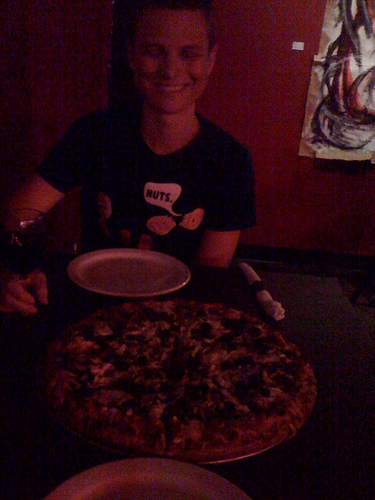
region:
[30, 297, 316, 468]
the pizza sitting on the table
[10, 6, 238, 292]
the guy sitting next to the table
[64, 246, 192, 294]
the plate sitting on the table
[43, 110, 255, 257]
the silly tshirt the man has on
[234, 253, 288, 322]
a rolled up napkin with a ring around it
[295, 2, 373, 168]
the piece of paper on the wall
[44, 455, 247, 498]
another white plate on the table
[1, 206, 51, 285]
the wine glass the man is holding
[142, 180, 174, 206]
the writing on the shirt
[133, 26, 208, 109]
the man's happy face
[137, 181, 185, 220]
speech bubble on a shirt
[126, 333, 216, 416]
cheese on a pizza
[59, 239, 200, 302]
circular white plate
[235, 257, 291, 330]
silverware in a napkin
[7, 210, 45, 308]
wine glass filled with red wine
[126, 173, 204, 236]
design on a t shirt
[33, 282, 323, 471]
pizza on a table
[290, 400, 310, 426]
crust on a pizza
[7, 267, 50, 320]
hand holding a wine stem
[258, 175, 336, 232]
wooden wall in a restaurant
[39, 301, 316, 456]
A pizza on the table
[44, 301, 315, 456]
The pizza is cooked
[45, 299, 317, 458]
The pizza is circular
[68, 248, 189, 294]
A plate on the table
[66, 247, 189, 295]
The plate is empty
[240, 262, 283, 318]
A napkin near the pizza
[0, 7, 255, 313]
A man at the table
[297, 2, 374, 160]
A painting on the wall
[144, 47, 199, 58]
The eyes of the man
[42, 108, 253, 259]
The man is wearing a black shirt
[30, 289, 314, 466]
Pizza with lots of olives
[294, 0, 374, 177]
abstract painting in background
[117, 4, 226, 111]
smiling person with eyes closed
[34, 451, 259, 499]
part of a plate can be seen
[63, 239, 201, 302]
empty plate in front of person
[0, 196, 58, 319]
the person's hand holds a glass of wine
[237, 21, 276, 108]
the walls appear red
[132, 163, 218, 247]
the word nuts on persons shirt with cartoon of nuts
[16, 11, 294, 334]
most of the image is red and very noisy/grainy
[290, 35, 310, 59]
small white square attached to wall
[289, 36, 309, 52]
a white sticker on the wall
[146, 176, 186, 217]
a conversation bubble on a t-shirt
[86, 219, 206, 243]
a peanut logo on shirt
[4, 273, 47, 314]
a hand holding a glass of wine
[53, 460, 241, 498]
an empty white plate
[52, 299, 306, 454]
a delicious pizza on the table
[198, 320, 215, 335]
ground sausage on the pizza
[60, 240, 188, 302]
an empty plate on the table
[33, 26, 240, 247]
a man sitting at a table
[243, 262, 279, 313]
silverware wrapped in a napkin